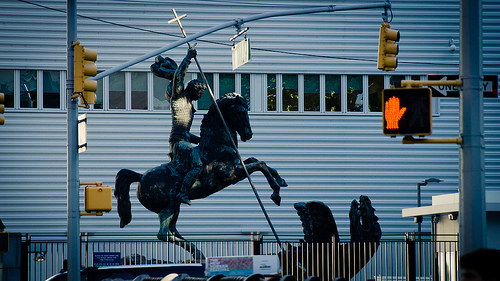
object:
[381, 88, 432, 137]
sign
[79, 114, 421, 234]
wall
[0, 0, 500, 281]
photo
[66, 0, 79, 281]
pole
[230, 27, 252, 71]
sign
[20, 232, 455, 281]
fence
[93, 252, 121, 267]
blue sign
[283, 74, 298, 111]
window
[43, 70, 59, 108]
window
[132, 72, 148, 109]
window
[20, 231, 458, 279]
poles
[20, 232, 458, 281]
gate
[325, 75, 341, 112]
window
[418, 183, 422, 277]
light pole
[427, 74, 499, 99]
street sign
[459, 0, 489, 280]
pole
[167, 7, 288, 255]
pole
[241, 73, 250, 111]
window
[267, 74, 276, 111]
window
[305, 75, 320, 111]
window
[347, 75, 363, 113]
window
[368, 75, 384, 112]
window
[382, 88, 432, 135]
donot walk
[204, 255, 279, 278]
signage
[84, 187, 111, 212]
walk light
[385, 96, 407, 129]
light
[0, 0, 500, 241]
ridges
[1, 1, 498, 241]
wall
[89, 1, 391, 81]
pole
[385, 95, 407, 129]
post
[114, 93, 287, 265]
horse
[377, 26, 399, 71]
light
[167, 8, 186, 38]
cross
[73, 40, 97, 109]
stop light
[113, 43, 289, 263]
statue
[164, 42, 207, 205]
man